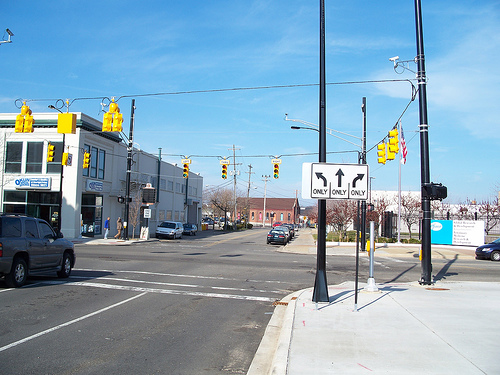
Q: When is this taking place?
A: Daytime.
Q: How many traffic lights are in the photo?
A: Eleven.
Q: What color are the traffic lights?
A: Yellow.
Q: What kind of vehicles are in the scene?
A: Cars.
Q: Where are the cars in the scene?
A: Street.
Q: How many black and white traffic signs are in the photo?
A: One.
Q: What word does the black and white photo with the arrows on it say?
A: Only.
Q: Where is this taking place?
A: At a city intersection.